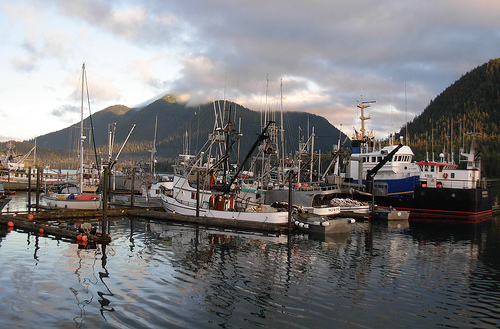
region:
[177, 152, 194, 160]
white revolving radar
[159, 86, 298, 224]
large white fishing boat with large cabin and outriggers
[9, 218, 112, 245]
section of floating dock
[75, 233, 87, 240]
orange inflatable dock bumpers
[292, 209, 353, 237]
fishing tender boat with white fishing floats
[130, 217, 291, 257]
reflection of fishing boat in the water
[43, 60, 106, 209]
sailing boat with tall mast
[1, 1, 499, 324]
fleet of fishing boats at dock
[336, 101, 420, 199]
large fishing boat with blue hull and white superstructure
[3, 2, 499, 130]
sky with fluffy white clouds and dark grey clouds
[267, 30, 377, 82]
Clouds in the photo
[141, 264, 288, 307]
Water in the photo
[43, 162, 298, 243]
Boats in the photo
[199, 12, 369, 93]
Cloudy skies in the photo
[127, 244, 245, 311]
Calm sea waters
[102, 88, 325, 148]
A hill in the background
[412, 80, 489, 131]
Trees on the hill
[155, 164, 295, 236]
White boat in the water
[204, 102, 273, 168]
Sails of boats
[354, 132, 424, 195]
Blue and white boat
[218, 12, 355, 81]
Clouds in the sky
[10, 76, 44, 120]
No clouds in this part of the sky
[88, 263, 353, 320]
The water is rippling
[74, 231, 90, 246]
Orange things on dock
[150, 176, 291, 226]
The boat is white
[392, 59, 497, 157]
A hill with trees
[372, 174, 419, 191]
Blue paint on boat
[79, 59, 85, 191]
Tallest boat mast of them all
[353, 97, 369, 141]
The mast is yellow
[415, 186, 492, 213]
The paint is black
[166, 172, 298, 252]
This is an engine boat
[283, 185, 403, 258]
This is an engine boat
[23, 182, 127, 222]
This is an engine boat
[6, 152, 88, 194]
This is an engine boat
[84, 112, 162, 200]
This is an engine boat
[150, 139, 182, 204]
This is an engine boat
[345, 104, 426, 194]
This is a ship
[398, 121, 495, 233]
This is a ship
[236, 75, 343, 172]
This is a mountain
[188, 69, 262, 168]
This is a mountain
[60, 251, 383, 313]
Rippling green lake water.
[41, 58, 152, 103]
Puffy white clouds in the sky.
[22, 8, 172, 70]
Blue sky with white clouds.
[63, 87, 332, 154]
Mountains in the distance.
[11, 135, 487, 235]
A marina filled with boats.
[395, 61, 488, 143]
Hill filled with trees.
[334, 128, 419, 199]
Large blue boat on the lake.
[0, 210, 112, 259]
Red water lake buoys.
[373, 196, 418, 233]
Little row boat on the water.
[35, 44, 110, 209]
A sailboat with no sails.